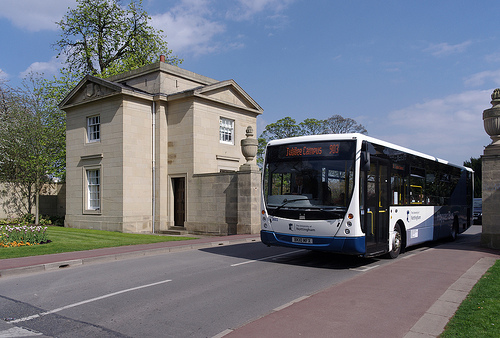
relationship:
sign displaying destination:
[265, 135, 362, 158] [284, 141, 328, 158]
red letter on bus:
[287, 146, 297, 153] [257, 133, 482, 257]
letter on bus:
[282, 146, 292, 159] [257, 133, 482, 257]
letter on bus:
[285, 147, 302, 157] [257, 133, 482, 257]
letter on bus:
[302, 147, 315, 156] [257, 133, 482, 257]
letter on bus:
[308, 147, 316, 156] [257, 133, 482, 257]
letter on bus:
[313, 147, 323, 155] [257, 133, 482, 257]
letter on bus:
[290, 144, 301, 158] [202, 100, 454, 304]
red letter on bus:
[284, 143, 340, 156] [257, 133, 482, 257]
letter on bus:
[294, 145, 306, 156] [254, 124, 481, 271]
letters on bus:
[280, 138, 344, 160] [231, 129, 481, 266]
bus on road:
[257, 133, 482, 257] [0, 222, 498, 336]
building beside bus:
[20, 50, 264, 290] [240, 86, 493, 303]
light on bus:
[277, 140, 343, 157] [259, 129, 473, 249]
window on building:
[81, 116, 104, 141] [53, 51, 268, 233]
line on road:
[7, 276, 175, 321] [2, 214, 482, 335]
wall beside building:
[184, 162, 264, 243] [53, 51, 268, 233]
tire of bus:
[385, 221, 406, 261] [257, 133, 482, 257]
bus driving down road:
[257, 133, 477, 261] [2, 227, 486, 332]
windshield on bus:
[268, 145, 365, 209] [257, 133, 482, 257]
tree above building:
[41, 3, 171, 64] [53, 51, 268, 233]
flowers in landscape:
[0, 221, 48, 248] [3, 220, 145, 273]